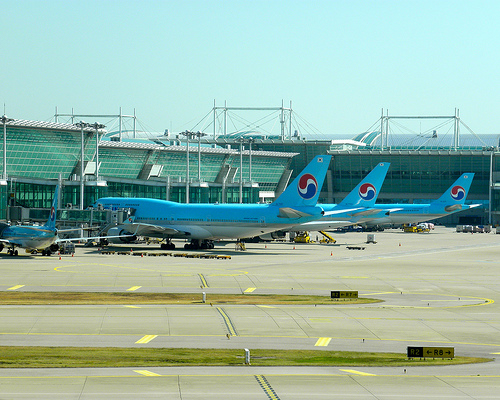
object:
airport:
[0, 0, 500, 400]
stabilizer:
[46, 170, 64, 233]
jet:
[94, 153, 485, 251]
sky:
[251, 28, 399, 76]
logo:
[295, 172, 317, 199]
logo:
[357, 182, 376, 199]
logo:
[449, 184, 465, 200]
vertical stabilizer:
[270, 152, 332, 205]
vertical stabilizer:
[335, 160, 391, 208]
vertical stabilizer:
[430, 171, 476, 203]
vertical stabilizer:
[43, 178, 60, 228]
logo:
[48, 205, 54, 222]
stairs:
[316, 225, 339, 250]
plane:
[0, 170, 135, 256]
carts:
[456, 222, 483, 233]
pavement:
[0, 225, 497, 398]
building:
[253, 85, 496, 218]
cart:
[213, 252, 233, 260]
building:
[0, 117, 113, 212]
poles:
[452, 107, 462, 149]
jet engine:
[103, 205, 150, 247]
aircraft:
[83, 153, 485, 250]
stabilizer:
[432, 172, 478, 208]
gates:
[15, 177, 256, 244]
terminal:
[2, 172, 293, 232]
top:
[102, 192, 269, 212]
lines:
[4, 260, 489, 398]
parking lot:
[0, 220, 492, 393]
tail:
[270, 154, 332, 199]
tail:
[438, 171, 474, 209]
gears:
[175, 228, 208, 242]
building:
[328, 101, 498, 231]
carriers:
[97, 246, 233, 261]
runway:
[0, 246, 500, 397]